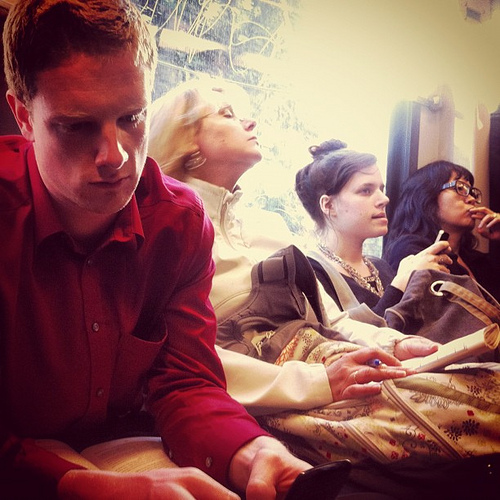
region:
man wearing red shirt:
[1, 1, 309, 499]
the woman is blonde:
[147, 72, 289, 222]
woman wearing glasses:
[388, 151, 498, 266]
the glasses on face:
[431, 172, 488, 204]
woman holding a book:
[277, 126, 494, 414]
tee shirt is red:
[4, 143, 276, 498]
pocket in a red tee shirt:
[117, 292, 175, 390]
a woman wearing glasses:
[440, 175, 487, 197]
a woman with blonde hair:
[152, 75, 234, 169]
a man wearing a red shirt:
[35, 175, 204, 443]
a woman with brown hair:
[283, 138, 368, 217]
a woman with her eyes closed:
[200, 88, 256, 161]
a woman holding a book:
[380, 321, 492, 373]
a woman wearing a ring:
[347, 366, 366, 388]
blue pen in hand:
[371, 358, 389, 370]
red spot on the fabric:
[456, 407, 485, 420]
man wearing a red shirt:
[15, 177, 224, 382]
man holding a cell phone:
[265, 448, 366, 488]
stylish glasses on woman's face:
[435, 168, 485, 203]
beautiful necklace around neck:
[317, 239, 422, 309]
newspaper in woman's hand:
[401, 307, 498, 382]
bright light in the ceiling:
[256, 27, 415, 149]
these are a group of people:
[20, 30, 448, 425]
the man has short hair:
[32, 8, 150, 216]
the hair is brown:
[22, 3, 153, 97]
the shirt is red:
[17, 161, 221, 429]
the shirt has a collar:
[18, 190, 172, 352]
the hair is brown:
[272, 117, 402, 241]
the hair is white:
[158, 83, 250, 177]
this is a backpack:
[228, 233, 362, 375]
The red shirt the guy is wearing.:
[0, 127, 252, 458]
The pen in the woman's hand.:
[366, 356, 382, 368]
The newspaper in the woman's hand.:
[390, 324, 496, 371]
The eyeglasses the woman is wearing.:
[446, 182, 481, 201]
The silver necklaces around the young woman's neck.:
[315, 244, 389, 295]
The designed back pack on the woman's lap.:
[229, 260, 499, 467]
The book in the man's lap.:
[37, 435, 212, 486]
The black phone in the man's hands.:
[293, 459, 350, 499]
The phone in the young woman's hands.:
[436, 229, 455, 246]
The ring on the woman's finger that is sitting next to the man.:
[353, 371, 356, 382]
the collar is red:
[21, 160, 65, 247]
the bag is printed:
[280, 330, 475, 463]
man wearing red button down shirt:
[2, 3, 283, 491]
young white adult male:
[3, 2, 307, 499]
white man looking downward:
[2, 3, 318, 498]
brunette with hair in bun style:
[287, 132, 392, 249]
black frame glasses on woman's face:
[437, 178, 484, 210]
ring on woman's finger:
[347, 365, 362, 388]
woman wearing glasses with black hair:
[382, 156, 499, 345]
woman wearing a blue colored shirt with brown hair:
[288, 122, 450, 344]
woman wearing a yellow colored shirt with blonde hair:
[136, 68, 443, 362]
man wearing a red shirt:
[3, 9, 324, 494]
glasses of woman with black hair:
[441, 179, 484, 201]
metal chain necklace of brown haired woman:
[316, 239, 391, 299]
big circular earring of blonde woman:
[185, 143, 214, 174]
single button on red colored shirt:
[89, 311, 103, 335]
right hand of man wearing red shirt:
[220, 421, 326, 496]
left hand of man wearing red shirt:
[77, 456, 224, 497]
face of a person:
[290, 139, 397, 242]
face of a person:
[138, 75, 260, 198]